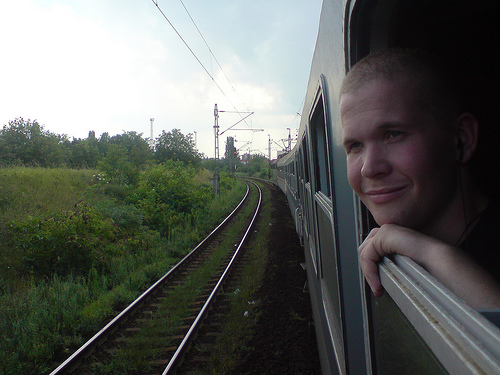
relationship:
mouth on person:
[358, 185, 410, 202] [336, 50, 496, 310]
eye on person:
[382, 127, 407, 142] [336, 50, 496, 310]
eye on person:
[345, 137, 367, 154] [336, 39, 498, 331]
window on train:
[301, 103, 344, 200] [275, 2, 497, 374]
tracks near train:
[39, 178, 269, 373] [275, 2, 497, 374]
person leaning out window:
[315, 58, 490, 315] [346, 0, 497, 331]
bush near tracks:
[4, 122, 68, 164] [39, 178, 269, 373]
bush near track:
[4, 122, 68, 164] [50, 173, 265, 371]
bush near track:
[96, 146, 152, 209] [50, 173, 265, 371]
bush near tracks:
[4, 122, 68, 164] [142, 200, 294, 364]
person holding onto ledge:
[315, 58, 490, 315] [358, 212, 498, 372]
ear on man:
[448, 113, 489, 165] [335, 43, 496, 332]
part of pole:
[213, 124, 220, 139] [213, 105, 219, 167]